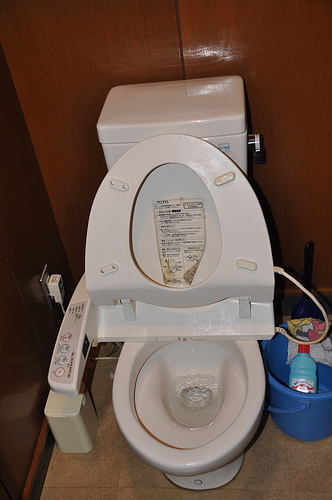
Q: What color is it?
A: White.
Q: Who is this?
A: No one.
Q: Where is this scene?
A: In a bathroom.